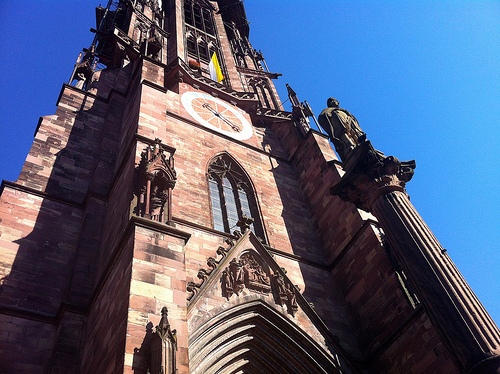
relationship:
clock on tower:
[175, 88, 259, 143] [10, 2, 498, 367]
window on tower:
[198, 147, 267, 244] [10, 2, 498, 367]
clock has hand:
[175, 88, 259, 143] [221, 116, 241, 133]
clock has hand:
[175, 88, 259, 143] [203, 99, 218, 117]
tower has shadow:
[10, 2, 498, 367] [7, 56, 146, 353]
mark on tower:
[54, 81, 65, 107] [10, 2, 498, 367]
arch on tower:
[193, 308, 332, 360] [10, 2, 498, 367]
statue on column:
[314, 93, 379, 166] [341, 179, 498, 360]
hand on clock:
[221, 116, 241, 133] [175, 88, 259, 143]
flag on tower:
[204, 49, 228, 85] [10, 2, 498, 367]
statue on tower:
[314, 93, 379, 166] [10, 2, 498, 367]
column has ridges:
[341, 179, 498, 360] [392, 207, 405, 218]